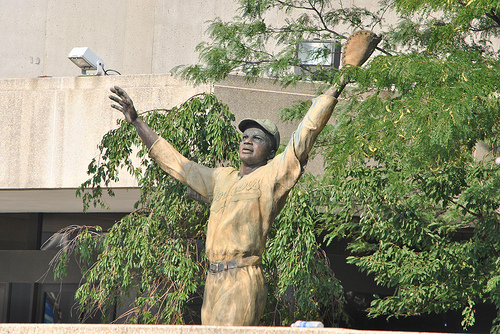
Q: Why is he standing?
A: Posing.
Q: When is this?
A: Daytime.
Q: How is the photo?
A: Clear.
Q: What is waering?
A: Hat.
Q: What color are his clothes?
A: Brown.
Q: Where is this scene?
A: Near a baseball park.